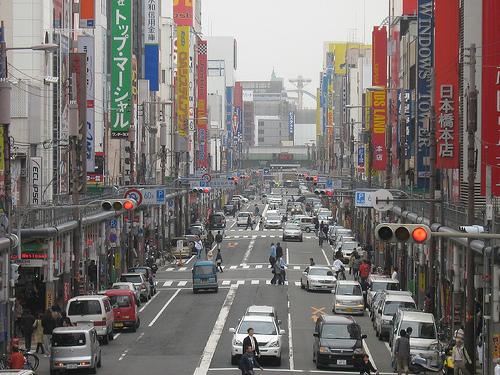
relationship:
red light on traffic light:
[408, 222, 429, 246] [222, 171, 242, 188]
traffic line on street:
[196, 277, 238, 374] [52, 172, 452, 372]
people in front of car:
[134, 223, 305, 291] [184, 291, 329, 362]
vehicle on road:
[228, 315, 287, 363] [37, 174, 402, 374]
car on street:
[233, 311, 285, 361] [125, 251, 387, 372]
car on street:
[326, 277, 368, 316] [15, 182, 420, 372]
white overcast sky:
[264, 31, 299, 56] [202, 2, 380, 124]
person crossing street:
[238, 324, 269, 364] [33, 170, 407, 365]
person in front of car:
[238, 324, 269, 364] [230, 315, 281, 359]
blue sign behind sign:
[416, 0, 433, 189] [431, 1, 463, 165]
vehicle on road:
[101, 287, 141, 331] [171, 294, 245, 371]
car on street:
[278, 251, 340, 292] [33, 170, 407, 365]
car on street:
[100, 287, 142, 334] [204, 282, 298, 344]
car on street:
[308, 309, 369, 373] [185, 302, 225, 354]